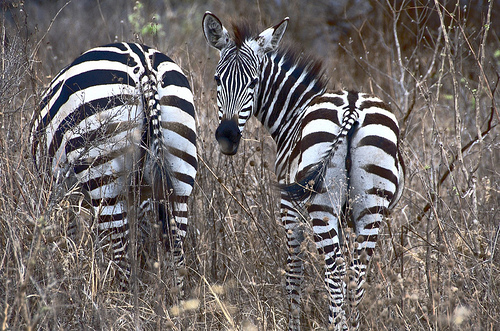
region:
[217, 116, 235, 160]
Zebra has black nose.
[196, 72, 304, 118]
Zebra has dark eyes.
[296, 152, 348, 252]
Zebra has dark hair on tip of tail.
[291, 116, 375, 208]
Zebra is black and white.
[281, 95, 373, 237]
Zebra is covered in stripes.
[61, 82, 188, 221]
Zebra is black and white.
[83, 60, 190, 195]
Zebra is covered in stripes.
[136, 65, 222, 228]
Zebra has black and white tial.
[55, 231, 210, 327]
Zebra is standing in tall grass.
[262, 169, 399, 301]
Zebra is standing in tall grass.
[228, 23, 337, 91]
the mane of a zebra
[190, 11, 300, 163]
zebra looking at the camera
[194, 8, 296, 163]
head of a zebra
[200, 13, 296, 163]
face of a zebra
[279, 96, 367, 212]
tail of a zebra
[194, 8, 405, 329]
a zebra on the right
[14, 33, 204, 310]
a zebra on the left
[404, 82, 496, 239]
a dark twig on the right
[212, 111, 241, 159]
the nose of the zebra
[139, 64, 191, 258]
tail of the left zebra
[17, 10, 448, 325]
Two zebras are together.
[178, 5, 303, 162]
The zebra is facing the camera.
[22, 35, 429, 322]
The zebras' rears are visible.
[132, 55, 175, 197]
The zebra's tail is black and white.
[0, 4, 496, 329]
The zebras are in tall vegetation.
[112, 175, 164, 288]
The zebra's head is bent down.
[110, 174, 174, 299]
The zebra is eating.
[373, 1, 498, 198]
The branches are bare.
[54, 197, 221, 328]
The vegetation hides the zebra's legs.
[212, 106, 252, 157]
The zebra's nose is black.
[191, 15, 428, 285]
the zebra looks at photographer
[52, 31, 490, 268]
two zebras are together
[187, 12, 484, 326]
this zebra is young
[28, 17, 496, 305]
the brush is dead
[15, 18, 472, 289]
the weather looks dry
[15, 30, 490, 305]
zebras are black and white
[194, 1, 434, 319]
the zebra's tail is whisking flies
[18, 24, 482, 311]
zebras have striped coats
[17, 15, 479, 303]
the zebras are wild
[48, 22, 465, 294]
zebras are in africa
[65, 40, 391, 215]
back ends of two zebras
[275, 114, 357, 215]
tail on back of zebra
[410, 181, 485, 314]
dried branches on ground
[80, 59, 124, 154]
black stripes on white body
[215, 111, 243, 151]
black snout on zebra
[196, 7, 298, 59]
two ears on head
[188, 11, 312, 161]
turned head on neck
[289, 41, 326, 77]
mane on zebra neck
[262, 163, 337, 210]
black hair on tail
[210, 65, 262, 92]
eyes on zebra face